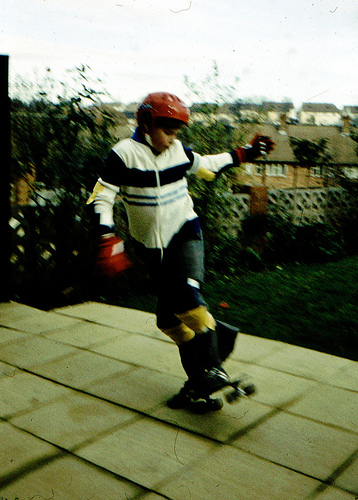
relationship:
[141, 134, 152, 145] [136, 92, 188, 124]
strap on helmet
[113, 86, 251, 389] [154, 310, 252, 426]
young boy on skateboard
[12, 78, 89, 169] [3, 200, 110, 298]
tree behind fence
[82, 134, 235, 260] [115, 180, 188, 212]
sweatshirt with stripes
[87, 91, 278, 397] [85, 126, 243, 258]
boy striped sweater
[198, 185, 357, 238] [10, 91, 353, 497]
fence in backyard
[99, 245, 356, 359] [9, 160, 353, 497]
grass in backyard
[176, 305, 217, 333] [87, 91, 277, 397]
kneepad on boy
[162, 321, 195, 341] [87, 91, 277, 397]
kneepad on boy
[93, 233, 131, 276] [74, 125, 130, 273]
glove on right hand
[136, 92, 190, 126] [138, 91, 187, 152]
helmet on head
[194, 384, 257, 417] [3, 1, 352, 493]
wheels up in air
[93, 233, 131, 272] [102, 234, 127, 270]
glove up in hand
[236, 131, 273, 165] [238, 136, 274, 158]
glove up in hand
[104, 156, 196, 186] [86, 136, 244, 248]
stripe in middle of sweater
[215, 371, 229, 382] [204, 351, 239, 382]
stripe on shoe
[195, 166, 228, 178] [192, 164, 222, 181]
patch on elbow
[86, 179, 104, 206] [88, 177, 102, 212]
patch on elbow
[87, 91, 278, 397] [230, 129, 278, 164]
boy wearing gloves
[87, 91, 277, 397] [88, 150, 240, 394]
boy looking down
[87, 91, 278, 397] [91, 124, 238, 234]
boy has a blue white and yellow jacket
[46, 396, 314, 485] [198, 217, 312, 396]
back deck of a house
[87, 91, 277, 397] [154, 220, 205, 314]
boy blue jeans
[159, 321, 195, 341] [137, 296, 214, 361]
kneepad on boys knee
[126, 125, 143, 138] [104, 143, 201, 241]
collar on boys sweater